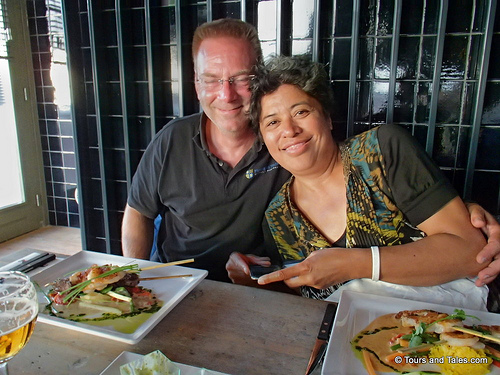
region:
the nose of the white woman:
[280, 117, 295, 132]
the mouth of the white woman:
[270, 135, 321, 150]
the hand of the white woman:
[265, 230, 490, 280]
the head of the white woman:
[255, 52, 340, 167]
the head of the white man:
[190, 18, 255, 127]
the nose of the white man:
[218, 87, 243, 106]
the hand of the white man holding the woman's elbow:
[455, 200, 497, 277]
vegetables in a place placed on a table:
[46, 267, 157, 322]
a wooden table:
[203, 277, 318, 371]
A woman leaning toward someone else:
[225, 52, 493, 314]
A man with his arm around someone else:
[119, 16, 499, 287]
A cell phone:
[247, 258, 284, 281]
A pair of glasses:
[192, 73, 259, 87]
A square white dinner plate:
[23, 248, 208, 344]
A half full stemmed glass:
[1, 269, 38, 374]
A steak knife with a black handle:
[304, 301, 336, 374]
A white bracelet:
[369, 245, 380, 280]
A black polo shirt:
[125, 112, 292, 284]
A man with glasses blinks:
[185, 17, 254, 139]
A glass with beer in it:
[1, 264, 56, 366]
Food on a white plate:
[317, 285, 491, 372]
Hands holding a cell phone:
[223, 238, 338, 292]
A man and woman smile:
[169, 17, 379, 197]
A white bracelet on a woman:
[361, 243, 388, 279]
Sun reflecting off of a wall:
[41, 42, 84, 119]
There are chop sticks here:
[157, 253, 169, 298]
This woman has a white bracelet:
[366, 252, 393, 290]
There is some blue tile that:
[51, 133, 68, 168]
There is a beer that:
[6, 323, 27, 358]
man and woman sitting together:
[121, 17, 498, 299]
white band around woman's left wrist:
[368, 244, 380, 281]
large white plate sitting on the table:
[26, 246, 208, 343]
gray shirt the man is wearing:
[126, 109, 288, 294]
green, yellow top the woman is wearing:
[260, 118, 456, 343]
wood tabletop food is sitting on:
[0, 247, 330, 373]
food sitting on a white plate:
[47, 269, 158, 324]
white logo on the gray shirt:
[243, 167, 255, 179]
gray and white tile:
[28, 1, 83, 231]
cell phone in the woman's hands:
[247, 262, 285, 277]